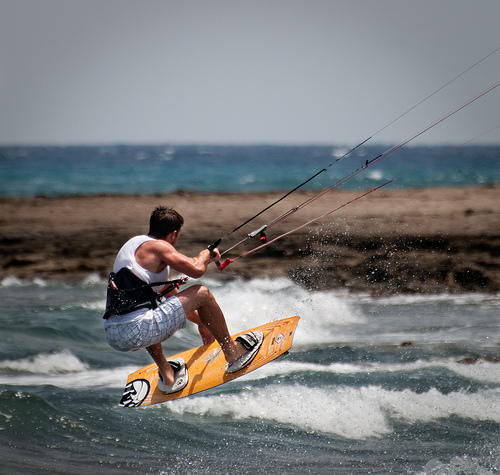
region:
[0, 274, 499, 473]
The water is rough.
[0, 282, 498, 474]
The water is sparkling.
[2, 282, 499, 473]
The water is glistening.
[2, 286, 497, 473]
The water is splashing.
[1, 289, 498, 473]
The water is shiny.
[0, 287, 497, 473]
The water is rambunctious.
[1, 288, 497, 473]
The water is zealous.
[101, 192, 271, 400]
The man has dark hair.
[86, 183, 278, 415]
The man's hair is short.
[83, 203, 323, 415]
The man is wearing shorts.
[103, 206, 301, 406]
a kite boarder catching air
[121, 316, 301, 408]
an orange kite board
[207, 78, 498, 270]
the kite control lines and handle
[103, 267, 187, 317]
the control line harness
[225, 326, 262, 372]
the kite board foot straps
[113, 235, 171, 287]
a white t-shirt on the kite boarder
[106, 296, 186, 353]
white checkered shorts on the kite boarder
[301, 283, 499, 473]
rough choppy water forming white splash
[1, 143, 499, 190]
rough choppy water in the distance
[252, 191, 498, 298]
a rocky shore line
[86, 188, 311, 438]
man going up on a parasail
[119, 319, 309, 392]
yellow surf board lifting off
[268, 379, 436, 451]
white cap on top of the wave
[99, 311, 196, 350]
swim trunks with stripes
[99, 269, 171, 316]
parasail harness on a man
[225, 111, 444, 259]
lines holding the parasail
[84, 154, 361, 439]
man learning to parasail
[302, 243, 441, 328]
waves crashing into the shore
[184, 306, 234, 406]
man hanging onto the board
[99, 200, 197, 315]
man on a white tank top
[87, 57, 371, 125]
hazy grayish white sky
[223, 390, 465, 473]
sprays of water in the air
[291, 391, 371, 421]
white foam in the ocean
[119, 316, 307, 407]
a yellow and white surfboard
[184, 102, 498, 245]
the strings of a water skiing kite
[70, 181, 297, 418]
a man water skiing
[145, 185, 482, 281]
brown dirt on the shore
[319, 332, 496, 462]
waves in the ocean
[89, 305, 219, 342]
white plate shorts on a man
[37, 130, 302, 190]
calm blue ocean in the distance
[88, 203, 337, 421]
man doing a water sport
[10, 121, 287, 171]
blue ocean water and horizen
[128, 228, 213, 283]
mans muscular right arm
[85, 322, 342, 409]
yellow board for water skiing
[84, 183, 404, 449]
man being towed on waterboard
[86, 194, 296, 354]
black waist harness for towing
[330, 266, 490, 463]
waves in the water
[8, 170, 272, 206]
blue water and shore line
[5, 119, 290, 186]
ocean water in shades of blue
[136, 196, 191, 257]
back of dark haired man's head